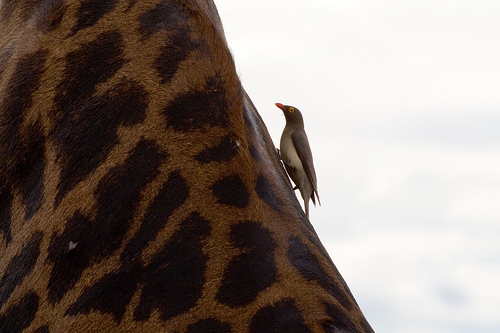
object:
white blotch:
[68, 241, 78, 250]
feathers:
[290, 130, 323, 209]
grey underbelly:
[280, 128, 304, 170]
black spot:
[158, 70, 234, 134]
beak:
[275, 102, 286, 111]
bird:
[273, 102, 322, 221]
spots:
[0, 50, 47, 333]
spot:
[207, 171, 251, 208]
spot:
[212, 218, 281, 309]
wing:
[291, 129, 321, 206]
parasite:
[272, 101, 321, 219]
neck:
[0, 0, 375, 333]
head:
[274, 102, 304, 124]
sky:
[214, 0, 500, 333]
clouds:
[214, 0, 500, 333]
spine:
[188, 0, 378, 333]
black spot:
[38, 134, 210, 324]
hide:
[0, 0, 378, 333]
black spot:
[189, 132, 240, 165]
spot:
[285, 233, 355, 313]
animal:
[0, 0, 372, 333]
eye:
[289, 107, 295, 113]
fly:
[66, 241, 78, 252]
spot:
[43, 29, 150, 217]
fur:
[0, 0, 378, 333]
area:
[185, 144, 297, 250]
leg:
[278, 151, 283, 160]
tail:
[302, 196, 309, 218]